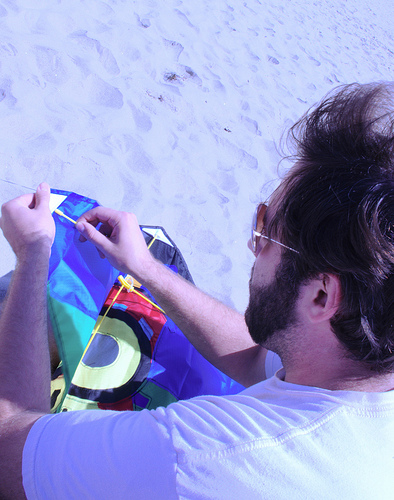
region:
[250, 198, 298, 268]
The glasses the man is wearing.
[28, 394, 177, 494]
The left sleeve of the man's t-shirt.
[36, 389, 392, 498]
The white t-shirt the man is wearing.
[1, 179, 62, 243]
The left hand of the man.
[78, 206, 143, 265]
The right hand of the man.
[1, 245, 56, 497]
The left arm of the man.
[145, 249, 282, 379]
The right arm of the man.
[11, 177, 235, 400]
The kite the man is fixing.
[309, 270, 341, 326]
The ear of the man.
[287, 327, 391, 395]
The neck of the man.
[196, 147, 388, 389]
man wearing sunglasses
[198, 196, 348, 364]
man with thick dark beard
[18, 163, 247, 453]
colorful graphic kite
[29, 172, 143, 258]
hands using a q-tip on the kite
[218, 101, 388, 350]
man with dark hair sticking up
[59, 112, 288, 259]
sand with foot prints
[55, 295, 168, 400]
blue white and black circle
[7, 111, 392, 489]
a man fixing a kite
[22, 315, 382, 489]
man wearing a white t-shirt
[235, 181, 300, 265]
rose colored glasses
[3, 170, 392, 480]
a man inserting a piece into a kite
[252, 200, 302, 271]
gold glasses on a man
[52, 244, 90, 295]
blue material on the inside of a kite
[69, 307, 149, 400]
a yellow and black curved loop in a kite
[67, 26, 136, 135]
footprints in the sand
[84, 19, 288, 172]
sand on a beach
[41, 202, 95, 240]
a yellow plastic stick in a kite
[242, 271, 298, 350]
a man's brown beard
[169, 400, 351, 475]
the seam on the shoulder of a man's white shirt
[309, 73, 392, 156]
a man's brown hair being blown upward by the wind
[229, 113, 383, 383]
man with facial hair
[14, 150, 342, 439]
man working on kite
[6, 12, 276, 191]
beach with small dunes and footsteps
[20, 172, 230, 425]
kite is multi-colored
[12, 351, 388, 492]
man wearing white t-shirt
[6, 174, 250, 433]
man assembling kite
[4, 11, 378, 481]
picture taken at daytime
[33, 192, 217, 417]
kite structure made of yellow plastic poles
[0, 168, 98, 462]
man holding item with left hand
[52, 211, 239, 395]
the kite is blue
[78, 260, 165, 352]
the kite is blue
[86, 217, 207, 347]
the kite is blue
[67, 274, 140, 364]
the kite is blue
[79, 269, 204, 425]
the kite is blue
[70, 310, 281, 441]
the kite is blue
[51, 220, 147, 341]
the kite is blue